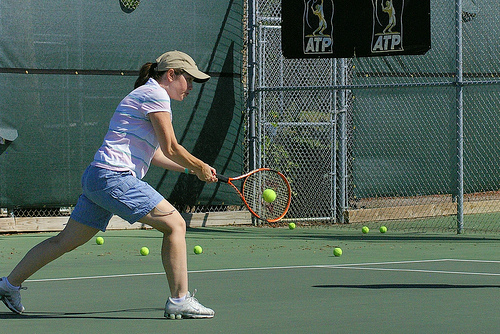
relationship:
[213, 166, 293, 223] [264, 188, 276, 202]
tennis racket hitting tennis ball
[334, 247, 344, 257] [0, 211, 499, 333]
tennis ball sitting on tennis court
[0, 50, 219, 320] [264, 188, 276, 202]
woman hitting tennis ball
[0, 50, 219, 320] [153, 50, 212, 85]
woman wearing baseball hat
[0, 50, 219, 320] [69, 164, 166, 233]
woman wearing shorts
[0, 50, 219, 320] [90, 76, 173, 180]
woman wearing shirt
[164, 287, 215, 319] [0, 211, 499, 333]
shoe standing on tennis court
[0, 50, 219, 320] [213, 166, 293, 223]
woman holding tennis racket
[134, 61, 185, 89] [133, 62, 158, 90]
hair held in ponytail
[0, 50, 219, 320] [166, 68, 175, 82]
woman has ear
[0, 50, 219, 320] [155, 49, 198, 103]
woman has head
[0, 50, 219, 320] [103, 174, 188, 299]
woman has leg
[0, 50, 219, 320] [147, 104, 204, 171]
woman has arm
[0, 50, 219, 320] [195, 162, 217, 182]
woman has hand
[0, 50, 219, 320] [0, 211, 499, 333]
woman playing on tennis court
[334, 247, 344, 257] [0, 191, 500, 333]
tennis ball laying on ground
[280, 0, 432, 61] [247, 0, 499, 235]
banner hanging on fence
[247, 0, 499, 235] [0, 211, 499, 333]
fence around tennis court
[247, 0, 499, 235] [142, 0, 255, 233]
fence has shadow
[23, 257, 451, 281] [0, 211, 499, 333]
line painted on tennis court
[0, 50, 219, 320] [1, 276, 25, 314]
woman wearing shoe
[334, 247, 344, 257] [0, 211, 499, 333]
tennis ball laying on tennis court